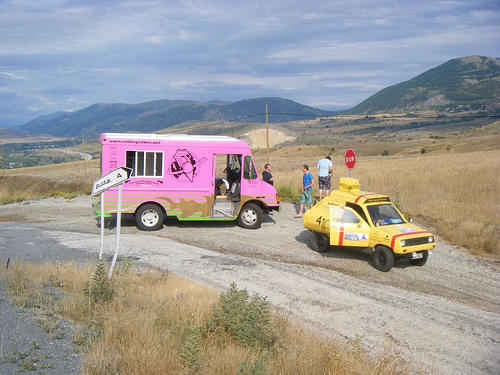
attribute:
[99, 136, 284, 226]
truck — pink, pink green, brown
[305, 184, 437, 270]
delivery car — yellow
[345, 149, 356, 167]
sign — red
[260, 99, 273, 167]
pole — brown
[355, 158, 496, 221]
grass — brown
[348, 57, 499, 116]
mountain — green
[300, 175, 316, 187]
shirt — blue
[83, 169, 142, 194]
sign — black, white, red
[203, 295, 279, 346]
shrub — green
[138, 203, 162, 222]
tire — black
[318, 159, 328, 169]
shirt — light blue